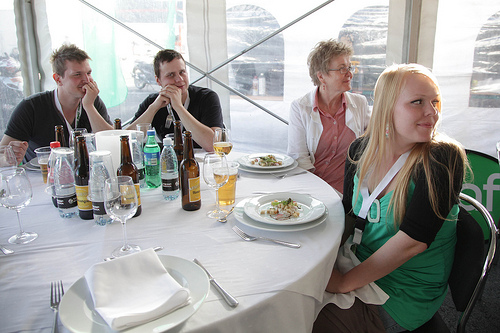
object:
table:
[0, 141, 344, 333]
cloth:
[0, 148, 392, 331]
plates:
[236, 152, 297, 169]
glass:
[211, 160, 240, 206]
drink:
[212, 171, 237, 205]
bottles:
[157, 137, 186, 203]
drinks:
[141, 140, 165, 187]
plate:
[243, 190, 327, 225]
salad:
[260, 196, 304, 222]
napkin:
[82, 247, 194, 331]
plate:
[48, 249, 208, 328]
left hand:
[81, 80, 98, 106]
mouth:
[175, 84, 185, 89]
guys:
[123, 48, 228, 153]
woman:
[309, 63, 463, 333]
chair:
[411, 190, 497, 332]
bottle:
[177, 131, 202, 212]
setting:
[55, 250, 211, 332]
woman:
[286, 35, 368, 188]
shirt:
[312, 96, 357, 197]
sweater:
[286, 87, 374, 175]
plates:
[231, 195, 329, 234]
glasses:
[102, 174, 140, 259]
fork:
[232, 225, 303, 248]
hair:
[347, 63, 477, 227]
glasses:
[323, 67, 357, 75]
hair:
[150, 48, 185, 81]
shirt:
[337, 132, 475, 332]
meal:
[246, 152, 285, 168]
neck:
[181, 131, 196, 158]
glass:
[0, 168, 41, 245]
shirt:
[129, 87, 230, 143]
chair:
[220, 121, 227, 141]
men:
[0, 41, 115, 166]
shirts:
[3, 88, 109, 165]